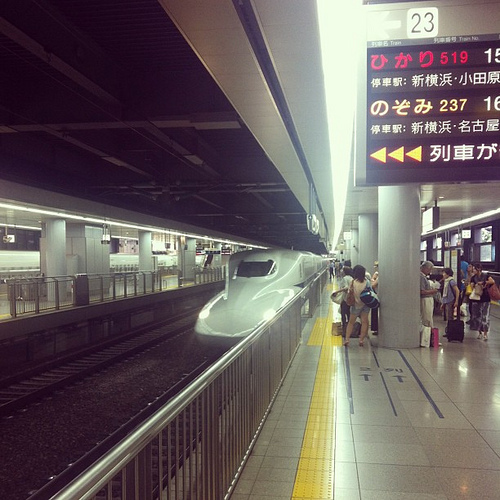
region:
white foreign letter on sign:
[371, 75, 382, 89]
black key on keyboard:
[379, 74, 391, 88]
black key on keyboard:
[389, 75, 403, 89]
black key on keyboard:
[410, 71, 427, 88]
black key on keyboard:
[423, 71, 438, 90]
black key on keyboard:
[437, 69, 452, 89]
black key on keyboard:
[456, 69, 471, 86]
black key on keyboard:
[471, 68, 485, 84]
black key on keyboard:
[428, 143, 450, 166]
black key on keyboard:
[453, 143, 474, 163]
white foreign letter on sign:
[370, 120, 382, 136]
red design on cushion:
[378, 121, 391, 135]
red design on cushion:
[391, 122, 401, 134]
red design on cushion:
[408, 118, 423, 134]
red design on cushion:
[423, 118, 438, 133]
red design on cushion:
[437, 118, 454, 136]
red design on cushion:
[455, 114, 472, 135]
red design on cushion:
[470, 116, 483, 131]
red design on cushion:
[428, 141, 452, 167]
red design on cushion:
[451, 141, 476, 165]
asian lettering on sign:
[366, 37, 498, 179]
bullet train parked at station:
[188, 242, 325, 354]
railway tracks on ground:
[4, 285, 239, 497]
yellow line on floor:
[287, 280, 347, 497]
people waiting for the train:
[331, 255, 497, 350]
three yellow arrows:
[367, 137, 427, 171]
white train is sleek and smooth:
[189, 241, 329, 350]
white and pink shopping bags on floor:
[417, 321, 443, 351]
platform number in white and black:
[403, 3, 442, 40]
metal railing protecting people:
[39, 261, 339, 498]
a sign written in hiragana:
[360, 55, 450, 76]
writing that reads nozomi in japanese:
[367, 96, 444, 118]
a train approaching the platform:
[187, 222, 305, 366]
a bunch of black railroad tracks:
[124, 249, 204, 431]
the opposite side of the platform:
[11, 201, 169, 313]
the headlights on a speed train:
[201, 303, 281, 334]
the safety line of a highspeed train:
[282, 368, 396, 436]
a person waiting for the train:
[337, 261, 388, 361]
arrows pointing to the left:
[362, 141, 434, 176]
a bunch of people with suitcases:
[425, 265, 477, 356]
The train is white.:
[184, 241, 334, 350]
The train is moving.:
[182, 220, 332, 370]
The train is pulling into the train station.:
[186, 217, 488, 459]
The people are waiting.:
[340, 259, 498, 329]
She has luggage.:
[438, 251, 464, 340]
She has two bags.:
[416, 256, 443, 354]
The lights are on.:
[353, 35, 495, 177]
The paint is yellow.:
[285, 291, 352, 487]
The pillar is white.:
[375, 174, 426, 350]